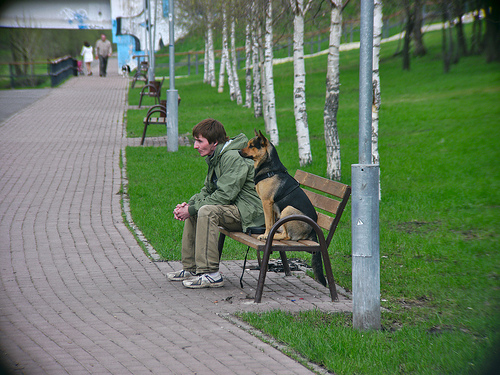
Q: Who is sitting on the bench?
A: A man and a dog.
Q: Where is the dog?
A: On the bench.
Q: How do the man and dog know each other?
A: Dog and master.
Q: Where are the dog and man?
A: In a park.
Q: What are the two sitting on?
A: A bench.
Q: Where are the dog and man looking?
A: To the left.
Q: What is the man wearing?
A: A green jacket.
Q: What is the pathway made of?
A: Bricks.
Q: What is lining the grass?
A: Trees.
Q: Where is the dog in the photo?
A: Bench.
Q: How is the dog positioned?
A: Sitting.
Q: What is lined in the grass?
A: White trees.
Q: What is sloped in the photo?
A: Grassy area.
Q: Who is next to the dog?
A: A man.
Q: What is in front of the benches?
A: Sidewalk/.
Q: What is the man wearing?
A: Green jacket.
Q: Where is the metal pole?
A: In grass.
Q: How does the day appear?
A: Chilly and clear.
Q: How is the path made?
A: With cobblestone.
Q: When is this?
A: Daytime.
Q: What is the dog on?
A: Bench.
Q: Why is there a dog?
A: Guarding.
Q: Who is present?
A: Person.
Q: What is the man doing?
A: Sitting.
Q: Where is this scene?
A: On the sidewalk.